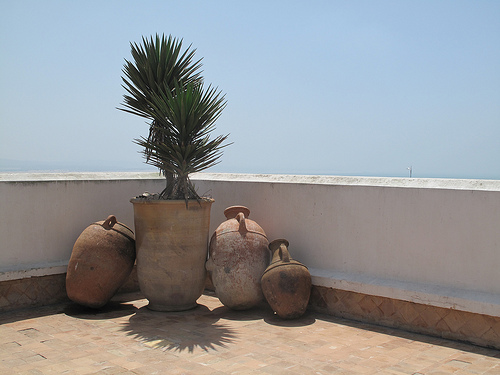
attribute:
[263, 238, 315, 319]
pot — clay, brown, small, old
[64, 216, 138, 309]
pot — empty, seperate, black marked, large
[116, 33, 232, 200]
plant — green, potted, sitting in corner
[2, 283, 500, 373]
ground — bricked, tiled, sinking down, tan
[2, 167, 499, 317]
wall — white, small, brown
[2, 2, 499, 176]
sky — bright, light blue, sunny, blue, clear, cloudless, bright blue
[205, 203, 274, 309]
pot — old, larger, made of clay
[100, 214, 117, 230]
handle — facing forward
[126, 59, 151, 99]
leaf — green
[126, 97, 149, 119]
leaf — green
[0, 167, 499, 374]
balcony — sunny, tiled, cement, painted white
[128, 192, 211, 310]
pot — large, clay, small, tan, light, in corner